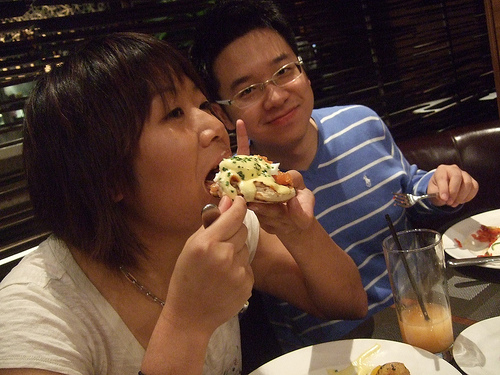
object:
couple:
[0, 15, 480, 373]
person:
[2, 32, 373, 375]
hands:
[163, 194, 259, 331]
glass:
[381, 227, 457, 354]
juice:
[398, 298, 457, 355]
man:
[176, 0, 482, 374]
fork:
[389, 190, 441, 209]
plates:
[437, 202, 500, 273]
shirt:
[212, 102, 445, 375]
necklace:
[105, 247, 166, 307]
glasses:
[214, 61, 307, 110]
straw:
[385, 212, 431, 320]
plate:
[242, 335, 467, 374]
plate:
[449, 310, 499, 374]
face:
[214, 31, 319, 154]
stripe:
[317, 134, 385, 170]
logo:
[359, 173, 377, 187]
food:
[210, 152, 300, 208]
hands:
[425, 163, 480, 208]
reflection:
[455, 278, 483, 288]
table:
[339, 266, 499, 342]